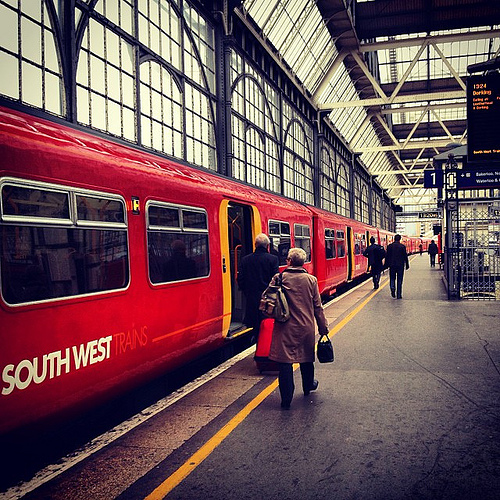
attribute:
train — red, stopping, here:
[2, 105, 388, 363]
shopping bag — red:
[243, 313, 283, 346]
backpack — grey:
[261, 282, 298, 325]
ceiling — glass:
[253, 19, 497, 155]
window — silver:
[149, 194, 237, 266]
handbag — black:
[304, 329, 349, 379]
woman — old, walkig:
[275, 234, 338, 421]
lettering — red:
[1, 342, 126, 400]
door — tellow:
[199, 170, 261, 350]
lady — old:
[272, 246, 359, 400]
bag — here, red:
[253, 307, 272, 363]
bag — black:
[294, 342, 356, 371]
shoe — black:
[297, 377, 338, 392]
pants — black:
[282, 344, 322, 402]